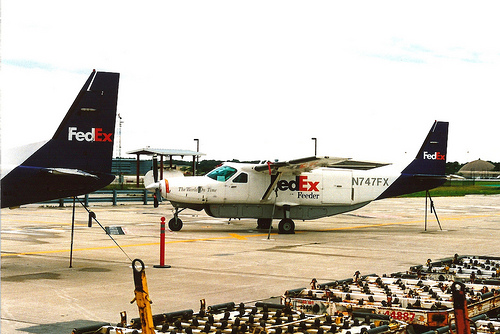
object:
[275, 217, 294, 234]
wheel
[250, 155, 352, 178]
wing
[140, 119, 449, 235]
plane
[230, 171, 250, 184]
window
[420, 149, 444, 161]
fed ex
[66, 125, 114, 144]
fed ex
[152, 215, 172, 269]
stand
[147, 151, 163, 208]
propeller